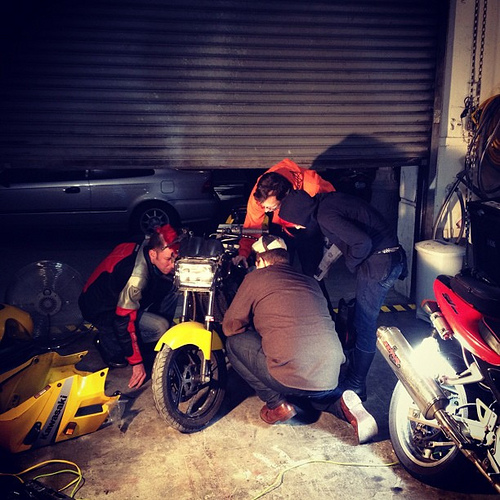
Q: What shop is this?
A: Mechanic shop.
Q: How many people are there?
A: 4.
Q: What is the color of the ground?
A: Brown.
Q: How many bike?
A: 2.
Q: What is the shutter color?
A: Grey.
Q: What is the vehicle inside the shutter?
A: Car.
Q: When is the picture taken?
A: Night time.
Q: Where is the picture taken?
A: In a garage.